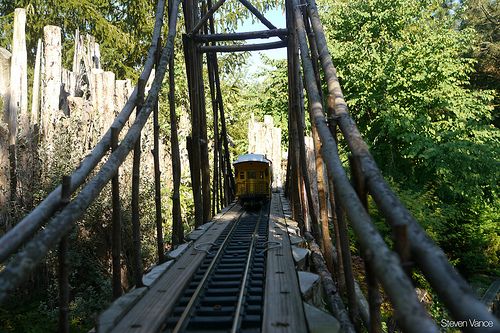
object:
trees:
[322, 2, 474, 169]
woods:
[246, 107, 255, 157]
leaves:
[90, 17, 105, 25]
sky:
[219, 4, 285, 59]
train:
[230, 152, 274, 202]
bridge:
[89, 190, 349, 332]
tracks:
[170, 214, 259, 331]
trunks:
[310, 133, 336, 267]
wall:
[0, 22, 132, 158]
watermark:
[437, 316, 488, 328]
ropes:
[209, 73, 216, 102]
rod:
[150, 6, 169, 23]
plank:
[260, 192, 305, 331]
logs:
[75, 164, 117, 209]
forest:
[245, 1, 499, 294]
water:
[318, 296, 341, 308]